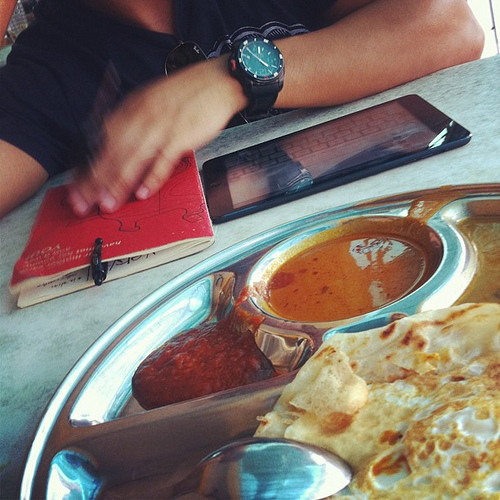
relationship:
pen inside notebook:
[90, 234, 108, 288] [5, 149, 215, 310]